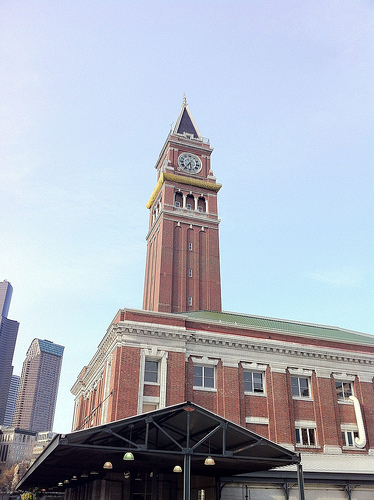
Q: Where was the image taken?
A: It was taken at the city.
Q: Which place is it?
A: It is a city.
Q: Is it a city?
A: Yes, it is a city.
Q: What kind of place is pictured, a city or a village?
A: It is a city.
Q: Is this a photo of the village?
A: No, the picture is showing the city.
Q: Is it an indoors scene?
A: Yes, it is indoors.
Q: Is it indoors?
A: Yes, it is indoors.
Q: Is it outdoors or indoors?
A: It is indoors.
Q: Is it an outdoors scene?
A: No, it is indoors.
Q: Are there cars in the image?
A: No, there are no cars.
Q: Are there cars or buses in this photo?
A: No, there are no cars or buses.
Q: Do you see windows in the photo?
A: Yes, there is a window.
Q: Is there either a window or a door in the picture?
A: Yes, there is a window.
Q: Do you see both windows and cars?
A: No, there is a window but no cars.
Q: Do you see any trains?
A: No, there are no trains.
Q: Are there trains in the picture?
A: No, there are no trains.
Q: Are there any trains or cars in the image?
A: No, there are no trains or cars.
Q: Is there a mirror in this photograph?
A: No, there are no mirrors.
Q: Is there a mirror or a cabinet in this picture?
A: No, there are no mirrors or cabinets.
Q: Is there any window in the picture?
A: Yes, there is a window.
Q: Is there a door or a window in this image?
A: Yes, there is a window.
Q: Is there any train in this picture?
A: No, there are no trains.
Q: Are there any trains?
A: No, there are no trains.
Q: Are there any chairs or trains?
A: No, there are no trains or chairs.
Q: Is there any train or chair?
A: No, there are no trains or chairs.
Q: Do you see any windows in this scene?
A: Yes, there is a window.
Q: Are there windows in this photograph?
A: Yes, there is a window.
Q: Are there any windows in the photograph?
A: Yes, there is a window.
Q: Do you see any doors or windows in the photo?
A: Yes, there is a window.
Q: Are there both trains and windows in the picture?
A: No, there is a window but no trains.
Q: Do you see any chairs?
A: No, there are no chairs.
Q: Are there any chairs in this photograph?
A: No, there are no chairs.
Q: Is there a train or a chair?
A: No, there are no chairs or trains.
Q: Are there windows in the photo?
A: Yes, there is a window.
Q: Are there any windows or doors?
A: Yes, there is a window.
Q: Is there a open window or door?
A: Yes, there is an open window.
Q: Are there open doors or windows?
A: Yes, there is an open window.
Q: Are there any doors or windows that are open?
A: Yes, the window is open.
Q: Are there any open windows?
A: Yes, there is an open window.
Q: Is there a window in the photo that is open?
A: Yes, there is a window that is open.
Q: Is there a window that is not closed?
A: Yes, there is a open window.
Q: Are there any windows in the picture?
A: Yes, there is a window.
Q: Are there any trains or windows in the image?
A: Yes, there is a window.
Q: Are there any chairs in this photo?
A: No, there are no chairs.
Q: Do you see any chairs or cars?
A: No, there are no chairs or cars.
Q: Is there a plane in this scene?
A: No, there are no airplanes.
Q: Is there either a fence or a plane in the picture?
A: No, there are no airplanes or fences.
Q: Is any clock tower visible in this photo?
A: Yes, there is a clock tower.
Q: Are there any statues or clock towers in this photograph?
A: Yes, there is a clock tower.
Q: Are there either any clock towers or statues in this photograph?
A: Yes, there is a clock tower.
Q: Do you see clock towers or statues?
A: Yes, there is a clock tower.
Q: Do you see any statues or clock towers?
A: Yes, there is a clock tower.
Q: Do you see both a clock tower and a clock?
A: Yes, there are both a clock tower and a clock.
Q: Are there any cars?
A: No, there are no cars.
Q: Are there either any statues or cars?
A: No, there are no cars or statues.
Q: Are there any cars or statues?
A: No, there are no cars or statues.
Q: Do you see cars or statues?
A: No, there are no cars or statues.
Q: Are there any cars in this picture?
A: No, there are no cars.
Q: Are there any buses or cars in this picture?
A: No, there are no cars or buses.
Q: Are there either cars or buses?
A: No, there are no cars or buses.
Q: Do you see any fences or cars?
A: No, there are no cars or fences.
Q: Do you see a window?
A: Yes, there are windows.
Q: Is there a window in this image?
A: Yes, there are windows.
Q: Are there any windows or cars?
A: Yes, there are windows.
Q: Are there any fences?
A: No, there are no fences.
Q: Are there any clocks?
A: Yes, there is a clock.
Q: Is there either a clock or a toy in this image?
A: Yes, there is a clock.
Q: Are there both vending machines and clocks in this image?
A: No, there is a clock but no vending machines.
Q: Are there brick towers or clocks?
A: Yes, there is a brick clock.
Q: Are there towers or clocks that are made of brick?
A: Yes, the clock is made of brick.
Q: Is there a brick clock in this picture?
A: Yes, there is a clock that is made of brick.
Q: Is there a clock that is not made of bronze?
A: Yes, there is a clock that is made of brick.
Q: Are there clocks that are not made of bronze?
A: Yes, there is a clock that is made of brick.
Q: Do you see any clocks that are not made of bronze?
A: Yes, there is a clock that is made of brick.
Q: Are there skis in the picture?
A: No, there are no skis.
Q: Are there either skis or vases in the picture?
A: No, there are no skis or vases.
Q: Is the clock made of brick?
A: Yes, the clock is made of brick.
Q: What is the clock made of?
A: The clock is made of brick.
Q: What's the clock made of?
A: The clock is made of brick.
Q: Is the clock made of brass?
A: No, the clock is made of brick.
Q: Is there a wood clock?
A: No, there is a clock but it is made of brick.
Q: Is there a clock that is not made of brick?
A: No, there is a clock but it is made of brick.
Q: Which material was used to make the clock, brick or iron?
A: The clock is made of brick.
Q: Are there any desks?
A: No, there are no desks.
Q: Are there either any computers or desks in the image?
A: No, there are no desks or computers.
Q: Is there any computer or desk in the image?
A: No, there are no desks or computers.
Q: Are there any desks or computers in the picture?
A: No, there are no desks or computers.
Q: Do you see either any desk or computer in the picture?
A: No, there are no desks or computers.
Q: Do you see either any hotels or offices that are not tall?
A: No, there is an office but it is tall.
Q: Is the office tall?
A: Yes, the office is tall.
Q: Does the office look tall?
A: Yes, the office is tall.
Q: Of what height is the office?
A: The office is tall.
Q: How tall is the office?
A: The office is tall.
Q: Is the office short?
A: No, the office is tall.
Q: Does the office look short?
A: No, the office is tall.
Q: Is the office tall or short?
A: The office is tall.